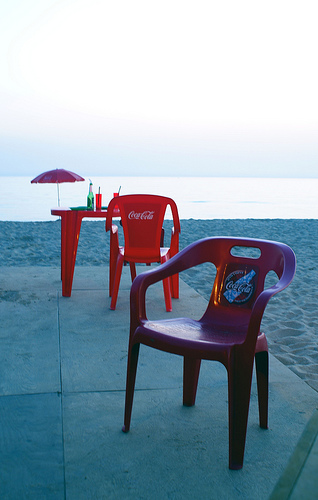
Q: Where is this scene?
A: The beach.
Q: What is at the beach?
A: Plastic chairs.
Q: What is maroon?
A: A plastic chair.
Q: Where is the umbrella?
A: Near the ocean.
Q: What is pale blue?
A: The sky.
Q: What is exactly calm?
A: The surface of water.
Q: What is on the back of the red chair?
A: A coco cola logo.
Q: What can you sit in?
A: The chair.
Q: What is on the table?
A: Drinks.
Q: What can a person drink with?
A: A straw.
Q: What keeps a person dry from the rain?
A: An umbrella.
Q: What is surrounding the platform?
A: Sand.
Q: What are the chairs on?
A: A cement pad.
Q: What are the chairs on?
A: A cement pad.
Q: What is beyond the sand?
A: The ocean.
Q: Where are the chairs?
A: By the sand.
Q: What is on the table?
A: Umbrella.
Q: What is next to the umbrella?
A: Drinks.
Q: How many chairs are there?
A: Two.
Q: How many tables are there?
A: One.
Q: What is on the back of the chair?
A: Coca-Cola.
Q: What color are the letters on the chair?
A: White.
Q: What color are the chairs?
A: Red.